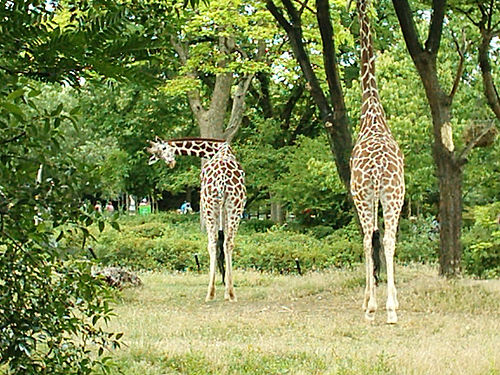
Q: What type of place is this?
A: It is a field.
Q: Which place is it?
A: It is a field.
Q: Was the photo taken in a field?
A: Yes, it was taken in a field.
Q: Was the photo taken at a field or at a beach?
A: It was taken at a field.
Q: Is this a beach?
A: No, it is a field.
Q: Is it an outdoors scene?
A: Yes, it is outdoors.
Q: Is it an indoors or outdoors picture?
A: It is outdoors.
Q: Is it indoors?
A: No, it is outdoors.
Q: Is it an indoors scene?
A: No, it is outdoors.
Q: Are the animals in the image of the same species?
A: Yes, all the animals are giraffes.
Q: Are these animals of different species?
A: No, all the animals are giraffes.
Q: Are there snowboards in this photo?
A: No, there are no snowboards.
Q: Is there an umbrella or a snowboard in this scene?
A: No, there are no snowboards or umbrellas.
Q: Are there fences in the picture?
A: No, there are no fences.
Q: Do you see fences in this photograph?
A: No, there are no fences.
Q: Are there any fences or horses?
A: No, there are no fences or horses.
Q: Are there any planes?
A: No, there are no planes.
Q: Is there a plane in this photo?
A: No, there are no airplanes.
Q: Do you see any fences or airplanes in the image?
A: No, there are no airplanes or fences.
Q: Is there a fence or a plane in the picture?
A: No, there are no airplanes or fences.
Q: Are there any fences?
A: No, there are no fences.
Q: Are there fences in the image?
A: No, there are no fences.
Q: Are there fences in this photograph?
A: No, there are no fences.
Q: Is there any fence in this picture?
A: No, there are no fences.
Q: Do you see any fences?
A: No, there are no fences.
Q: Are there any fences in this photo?
A: No, there are no fences.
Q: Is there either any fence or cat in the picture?
A: No, there are no fences or cats.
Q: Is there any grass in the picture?
A: Yes, there is grass.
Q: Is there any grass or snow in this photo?
A: Yes, there is grass.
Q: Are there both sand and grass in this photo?
A: No, there is grass but no sand.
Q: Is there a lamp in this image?
A: No, there are no lamps.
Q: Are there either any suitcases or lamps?
A: No, there are no lamps or suitcases.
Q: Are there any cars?
A: No, there are no cars.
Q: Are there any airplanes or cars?
A: No, there are no cars or airplanes.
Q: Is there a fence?
A: No, there are no fences.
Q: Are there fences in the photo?
A: No, there are no fences.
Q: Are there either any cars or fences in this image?
A: No, there are no fences or cars.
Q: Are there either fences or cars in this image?
A: No, there are no fences or cars.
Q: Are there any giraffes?
A: Yes, there is a giraffe.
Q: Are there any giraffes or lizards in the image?
A: Yes, there is a giraffe.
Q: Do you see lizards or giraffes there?
A: Yes, there is a giraffe.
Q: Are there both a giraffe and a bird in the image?
A: No, there is a giraffe but no birds.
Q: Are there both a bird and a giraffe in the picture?
A: No, there is a giraffe but no birds.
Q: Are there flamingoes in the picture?
A: No, there are no flamingoes.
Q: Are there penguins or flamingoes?
A: No, there are no flamingoes or penguins.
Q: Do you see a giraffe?
A: Yes, there are giraffes.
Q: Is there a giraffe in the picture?
A: Yes, there are giraffes.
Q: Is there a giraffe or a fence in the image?
A: Yes, there are giraffes.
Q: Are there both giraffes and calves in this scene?
A: No, there are giraffes but no calves.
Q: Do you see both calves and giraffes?
A: No, there are giraffes but no calves.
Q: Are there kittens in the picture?
A: No, there are no kittens.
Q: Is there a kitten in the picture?
A: No, there are no kittens.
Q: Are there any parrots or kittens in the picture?
A: No, there are no kittens or parrots.